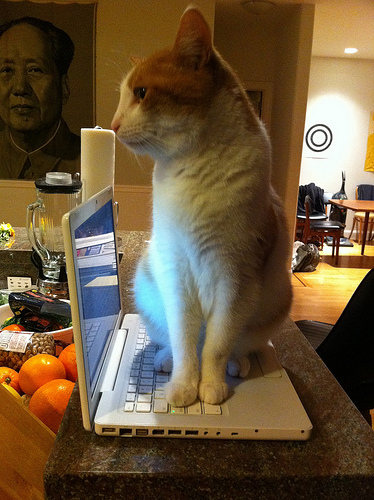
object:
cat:
[109, 3, 296, 409]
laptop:
[60, 183, 314, 442]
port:
[101, 427, 116, 434]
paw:
[196, 378, 230, 405]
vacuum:
[323, 168, 354, 248]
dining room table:
[327, 198, 374, 259]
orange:
[17, 351, 68, 396]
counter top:
[0, 225, 374, 500]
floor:
[289, 239, 374, 326]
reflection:
[131, 192, 199, 379]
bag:
[0, 329, 58, 374]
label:
[0, 328, 36, 355]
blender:
[25, 169, 83, 301]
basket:
[0, 381, 59, 500]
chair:
[302, 193, 347, 267]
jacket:
[297, 182, 326, 215]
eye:
[134, 84, 149, 105]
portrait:
[0, 0, 98, 181]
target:
[305, 122, 334, 153]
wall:
[299, 55, 374, 243]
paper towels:
[79, 125, 118, 205]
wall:
[2, 0, 215, 235]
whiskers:
[133, 149, 148, 175]